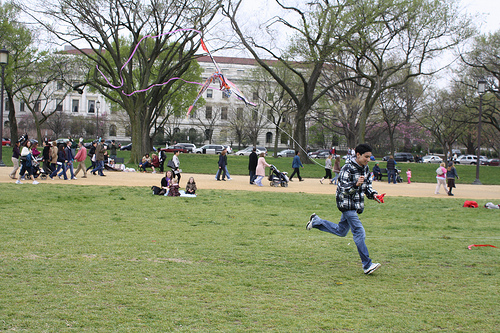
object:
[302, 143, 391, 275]
boy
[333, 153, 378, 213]
flannel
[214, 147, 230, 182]
man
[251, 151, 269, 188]
woman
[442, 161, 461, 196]
females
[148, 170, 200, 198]
family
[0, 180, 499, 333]
grass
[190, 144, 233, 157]
cars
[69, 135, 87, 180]
people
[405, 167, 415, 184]
child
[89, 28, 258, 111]
kite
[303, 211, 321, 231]
shoe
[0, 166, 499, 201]
path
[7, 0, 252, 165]
trees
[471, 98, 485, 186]
post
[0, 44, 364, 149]
building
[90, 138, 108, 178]
person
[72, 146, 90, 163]
jacket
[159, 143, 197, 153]
car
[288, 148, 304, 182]
man